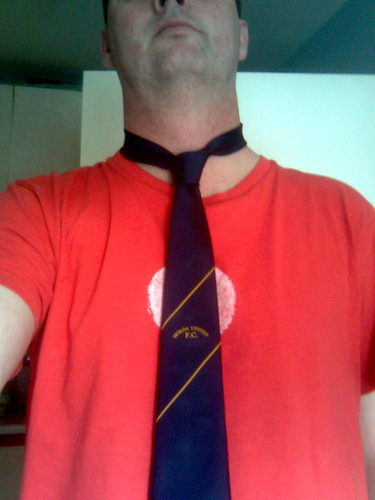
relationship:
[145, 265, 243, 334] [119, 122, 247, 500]
white spot behind blue/gold tie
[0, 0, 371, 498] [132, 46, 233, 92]
man has a chin chin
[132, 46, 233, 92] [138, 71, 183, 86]
chin has a stubble beard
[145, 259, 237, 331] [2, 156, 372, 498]
white spot on a shirt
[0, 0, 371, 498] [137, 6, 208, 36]
man with a mustache stubble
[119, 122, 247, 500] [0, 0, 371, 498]
blue/gold tie around man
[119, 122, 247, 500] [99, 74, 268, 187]
blue/gold tie around man neck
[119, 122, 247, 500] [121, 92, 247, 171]
blue/gold tie on neck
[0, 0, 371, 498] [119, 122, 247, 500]
man has blue/gold tie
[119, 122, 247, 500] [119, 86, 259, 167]
blue/gold tie on neck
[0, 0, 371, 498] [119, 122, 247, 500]
man wearing a blue/gold tie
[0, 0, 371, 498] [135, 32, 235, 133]
man has chin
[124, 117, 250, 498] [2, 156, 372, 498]
necktie with shirt